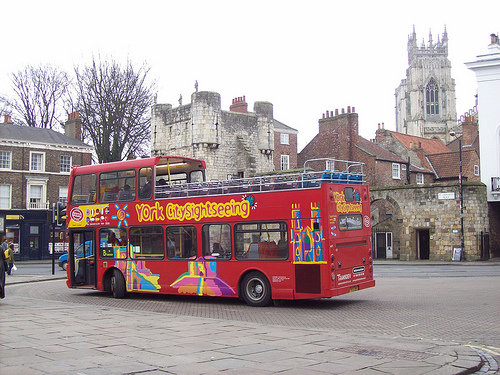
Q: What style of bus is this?
A: Double-decker bus.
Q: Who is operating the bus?
A: Bus driver.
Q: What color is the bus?
A: Red.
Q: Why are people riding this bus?
A: Sightseeing.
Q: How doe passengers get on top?
A: Climb stairs.